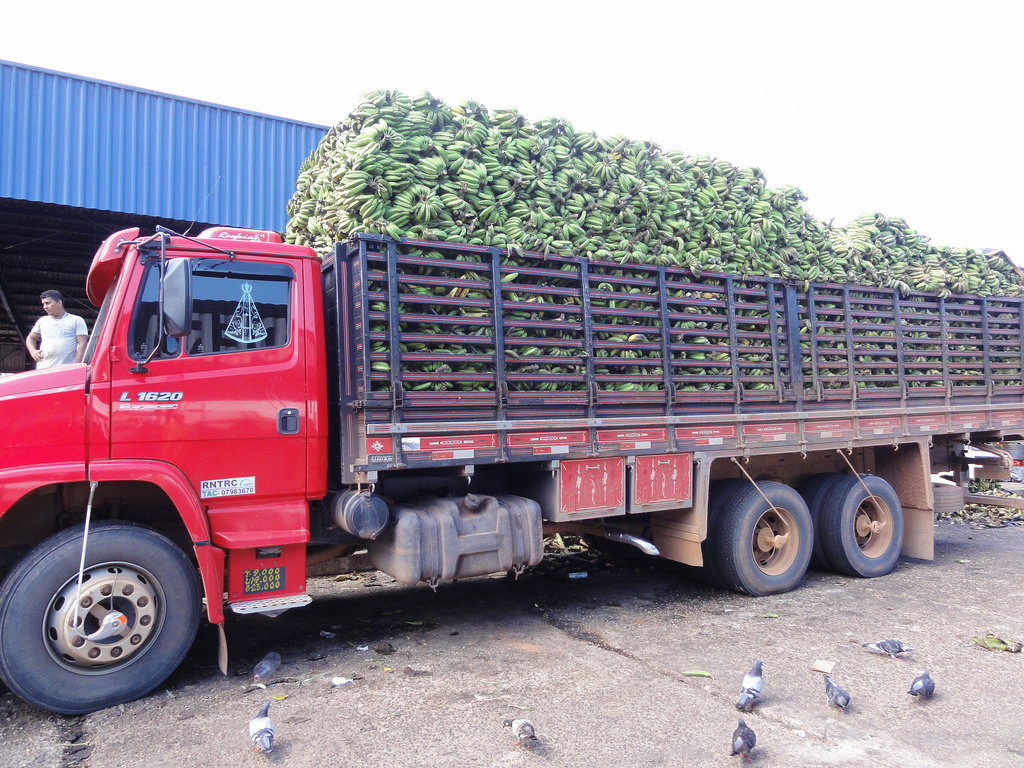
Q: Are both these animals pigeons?
A: Yes, all the animals are pigeons.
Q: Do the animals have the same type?
A: Yes, all the animals are pigeons.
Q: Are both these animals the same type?
A: Yes, all the animals are pigeons.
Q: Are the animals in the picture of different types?
A: No, all the animals are pigeons.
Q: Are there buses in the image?
A: No, there are no buses.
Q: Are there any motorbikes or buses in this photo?
A: No, there are no buses or motorbikes.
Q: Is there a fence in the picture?
A: No, there are no fences.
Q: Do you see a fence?
A: No, there are no fences.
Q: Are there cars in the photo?
A: No, there are no cars.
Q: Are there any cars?
A: No, there are no cars.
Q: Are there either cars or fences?
A: No, there are no cars or fences.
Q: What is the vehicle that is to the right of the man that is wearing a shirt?
A: The vehicle is a trailer.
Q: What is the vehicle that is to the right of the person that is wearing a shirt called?
A: The vehicle is a trailer.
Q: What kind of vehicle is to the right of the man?
A: The vehicle is a trailer.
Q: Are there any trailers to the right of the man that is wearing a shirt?
A: Yes, there is a trailer to the right of the man.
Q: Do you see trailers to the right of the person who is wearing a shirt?
A: Yes, there is a trailer to the right of the man.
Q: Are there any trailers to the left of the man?
A: No, the trailer is to the right of the man.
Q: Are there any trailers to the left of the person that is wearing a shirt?
A: No, the trailer is to the right of the man.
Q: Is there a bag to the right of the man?
A: No, there is a trailer to the right of the man.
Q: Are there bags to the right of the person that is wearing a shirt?
A: No, there is a trailer to the right of the man.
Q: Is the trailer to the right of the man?
A: Yes, the trailer is to the right of the man.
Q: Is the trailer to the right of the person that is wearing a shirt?
A: Yes, the trailer is to the right of the man.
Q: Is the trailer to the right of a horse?
A: No, the trailer is to the right of the man.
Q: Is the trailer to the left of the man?
A: No, the trailer is to the right of the man.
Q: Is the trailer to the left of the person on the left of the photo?
A: No, the trailer is to the right of the man.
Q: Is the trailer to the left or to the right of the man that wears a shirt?
A: The trailer is to the right of the man.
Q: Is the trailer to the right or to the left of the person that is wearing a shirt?
A: The trailer is to the right of the man.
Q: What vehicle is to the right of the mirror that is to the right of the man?
A: The vehicle is a trailer.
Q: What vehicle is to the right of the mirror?
A: The vehicle is a trailer.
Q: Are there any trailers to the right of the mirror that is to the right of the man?
A: Yes, there is a trailer to the right of the mirror.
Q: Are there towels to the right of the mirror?
A: No, there is a trailer to the right of the mirror.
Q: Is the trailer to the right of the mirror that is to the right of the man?
A: Yes, the trailer is to the right of the mirror.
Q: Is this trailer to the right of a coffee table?
A: No, the trailer is to the right of the mirror.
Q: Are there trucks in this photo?
A: Yes, there is a truck.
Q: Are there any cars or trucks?
A: Yes, there is a truck.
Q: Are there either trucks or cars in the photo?
A: Yes, there is a truck.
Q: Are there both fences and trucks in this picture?
A: No, there is a truck but no fences.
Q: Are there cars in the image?
A: No, there are no cars.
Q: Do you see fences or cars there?
A: No, there are no cars or fences.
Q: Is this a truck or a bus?
A: This is a truck.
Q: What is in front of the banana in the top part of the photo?
A: The truck is in front of the banana.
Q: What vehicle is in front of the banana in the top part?
A: The vehicle is a truck.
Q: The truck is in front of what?
A: The truck is in front of the banana.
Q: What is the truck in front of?
A: The truck is in front of the banana.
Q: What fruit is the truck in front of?
A: The truck is in front of the banana.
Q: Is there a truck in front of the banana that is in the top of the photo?
A: Yes, there is a truck in front of the banana.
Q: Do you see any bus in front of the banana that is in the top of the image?
A: No, there is a truck in front of the banana.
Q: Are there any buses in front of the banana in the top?
A: No, there is a truck in front of the banana.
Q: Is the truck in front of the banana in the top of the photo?
A: Yes, the truck is in front of the banana.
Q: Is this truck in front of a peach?
A: No, the truck is in front of the banana.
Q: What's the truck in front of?
A: The truck is in front of the banana.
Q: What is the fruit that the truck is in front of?
A: The fruit is a banana.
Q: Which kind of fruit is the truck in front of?
A: The truck is in front of the banana.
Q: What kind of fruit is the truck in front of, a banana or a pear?
A: The truck is in front of a banana.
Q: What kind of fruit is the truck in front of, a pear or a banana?
A: The truck is in front of a banana.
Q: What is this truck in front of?
A: The truck is in front of the banana.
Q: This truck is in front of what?
A: The truck is in front of the banana.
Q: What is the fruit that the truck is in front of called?
A: The fruit is a banana.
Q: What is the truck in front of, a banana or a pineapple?
A: The truck is in front of a banana.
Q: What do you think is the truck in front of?
A: The truck is in front of the banana.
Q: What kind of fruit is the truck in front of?
A: The truck is in front of the banana.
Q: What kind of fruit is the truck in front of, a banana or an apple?
A: The truck is in front of a banana.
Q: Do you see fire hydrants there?
A: No, there are no fire hydrants.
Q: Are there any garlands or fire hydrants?
A: No, there are no fire hydrants or garlands.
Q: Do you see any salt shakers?
A: No, there are no salt shakers.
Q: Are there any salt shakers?
A: No, there are no salt shakers.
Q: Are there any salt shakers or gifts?
A: No, there are no salt shakers or gifts.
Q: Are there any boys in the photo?
A: No, there are no boys.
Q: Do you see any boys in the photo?
A: No, there are no boys.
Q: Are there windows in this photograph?
A: Yes, there is a window.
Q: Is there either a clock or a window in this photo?
A: Yes, there is a window.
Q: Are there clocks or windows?
A: Yes, there is a window.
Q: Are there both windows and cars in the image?
A: No, there is a window but no cars.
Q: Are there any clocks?
A: No, there are no clocks.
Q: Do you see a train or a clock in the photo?
A: No, there are no clocks or trains.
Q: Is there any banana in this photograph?
A: Yes, there is a banana.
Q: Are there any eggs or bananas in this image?
A: Yes, there is a banana.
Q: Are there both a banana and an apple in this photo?
A: No, there is a banana but no apples.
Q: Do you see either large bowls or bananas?
A: Yes, there is a large banana.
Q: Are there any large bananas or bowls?
A: Yes, there is a large banana.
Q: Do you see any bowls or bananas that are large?
A: Yes, the banana is large.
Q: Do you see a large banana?
A: Yes, there is a large banana.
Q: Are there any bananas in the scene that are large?
A: Yes, there is a banana that is large.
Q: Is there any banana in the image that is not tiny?
A: Yes, there is a large banana.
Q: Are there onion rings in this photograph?
A: No, there are no onion rings.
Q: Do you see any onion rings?
A: No, there are no onion rings.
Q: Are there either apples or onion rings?
A: No, there are no onion rings or apples.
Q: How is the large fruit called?
A: The fruit is a banana.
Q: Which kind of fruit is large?
A: The fruit is a banana.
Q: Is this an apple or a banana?
A: This is a banana.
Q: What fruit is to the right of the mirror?
A: The fruit is a banana.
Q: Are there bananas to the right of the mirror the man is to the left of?
A: Yes, there is a banana to the right of the mirror.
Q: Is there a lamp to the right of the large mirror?
A: No, there is a banana to the right of the mirror.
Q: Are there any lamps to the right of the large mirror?
A: No, there is a banana to the right of the mirror.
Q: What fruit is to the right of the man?
A: The fruit is a banana.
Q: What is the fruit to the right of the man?
A: The fruit is a banana.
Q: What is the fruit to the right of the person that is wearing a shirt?
A: The fruit is a banana.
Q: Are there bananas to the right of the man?
A: Yes, there is a banana to the right of the man.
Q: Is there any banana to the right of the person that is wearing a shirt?
A: Yes, there is a banana to the right of the man.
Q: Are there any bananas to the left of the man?
A: No, the banana is to the right of the man.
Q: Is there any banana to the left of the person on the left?
A: No, the banana is to the right of the man.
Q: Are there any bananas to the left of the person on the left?
A: No, the banana is to the right of the man.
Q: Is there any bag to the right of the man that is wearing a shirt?
A: No, there is a banana to the right of the man.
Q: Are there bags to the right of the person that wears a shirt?
A: No, there is a banana to the right of the man.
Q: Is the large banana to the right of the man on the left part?
A: Yes, the banana is to the right of the man.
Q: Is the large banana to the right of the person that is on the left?
A: Yes, the banana is to the right of the man.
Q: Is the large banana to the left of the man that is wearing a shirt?
A: No, the banana is to the right of the man.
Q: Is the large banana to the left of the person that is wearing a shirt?
A: No, the banana is to the right of the man.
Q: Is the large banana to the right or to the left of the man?
A: The banana is to the right of the man.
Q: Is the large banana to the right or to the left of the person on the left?
A: The banana is to the right of the man.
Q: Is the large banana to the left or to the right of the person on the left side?
A: The banana is to the right of the man.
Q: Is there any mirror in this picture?
A: Yes, there is a mirror.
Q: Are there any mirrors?
A: Yes, there is a mirror.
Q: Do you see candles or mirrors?
A: Yes, there is a mirror.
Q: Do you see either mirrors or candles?
A: Yes, there is a mirror.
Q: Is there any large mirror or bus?
A: Yes, there is a large mirror.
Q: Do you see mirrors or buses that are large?
A: Yes, the mirror is large.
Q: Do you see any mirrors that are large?
A: Yes, there is a large mirror.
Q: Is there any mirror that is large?
A: Yes, there is a mirror that is large.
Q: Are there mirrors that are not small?
A: Yes, there is a large mirror.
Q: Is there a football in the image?
A: No, there are no footballs.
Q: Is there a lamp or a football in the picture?
A: No, there are no footballs or lamps.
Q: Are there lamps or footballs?
A: No, there are no footballs or lamps.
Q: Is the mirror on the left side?
A: Yes, the mirror is on the left of the image.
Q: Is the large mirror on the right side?
A: No, the mirror is on the left of the image.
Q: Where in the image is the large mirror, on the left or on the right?
A: The mirror is on the left of the image.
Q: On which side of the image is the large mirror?
A: The mirror is on the left of the image.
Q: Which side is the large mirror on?
A: The mirror is on the left of the image.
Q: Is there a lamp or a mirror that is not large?
A: No, there is a mirror but it is large.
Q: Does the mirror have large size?
A: Yes, the mirror is large.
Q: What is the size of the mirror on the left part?
A: The mirror is large.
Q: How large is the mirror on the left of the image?
A: The mirror is large.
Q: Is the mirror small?
A: No, the mirror is large.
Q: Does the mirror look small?
A: No, the mirror is large.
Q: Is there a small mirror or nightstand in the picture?
A: No, there is a mirror but it is large.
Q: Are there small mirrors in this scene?
A: No, there is a mirror but it is large.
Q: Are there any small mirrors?
A: No, there is a mirror but it is large.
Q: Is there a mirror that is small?
A: No, there is a mirror but it is large.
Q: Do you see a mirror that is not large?
A: No, there is a mirror but it is large.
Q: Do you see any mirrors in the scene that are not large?
A: No, there is a mirror but it is large.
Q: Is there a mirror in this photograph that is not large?
A: No, there is a mirror but it is large.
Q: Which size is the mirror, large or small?
A: The mirror is large.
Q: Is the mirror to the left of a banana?
A: Yes, the mirror is to the left of a banana.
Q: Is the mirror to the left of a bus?
A: No, the mirror is to the left of a banana.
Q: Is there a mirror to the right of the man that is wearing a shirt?
A: Yes, there is a mirror to the right of the man.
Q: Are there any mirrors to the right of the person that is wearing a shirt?
A: Yes, there is a mirror to the right of the man.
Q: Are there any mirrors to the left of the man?
A: No, the mirror is to the right of the man.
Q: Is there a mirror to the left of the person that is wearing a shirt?
A: No, the mirror is to the right of the man.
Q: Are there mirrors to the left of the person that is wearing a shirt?
A: No, the mirror is to the right of the man.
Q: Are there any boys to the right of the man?
A: No, there is a mirror to the right of the man.